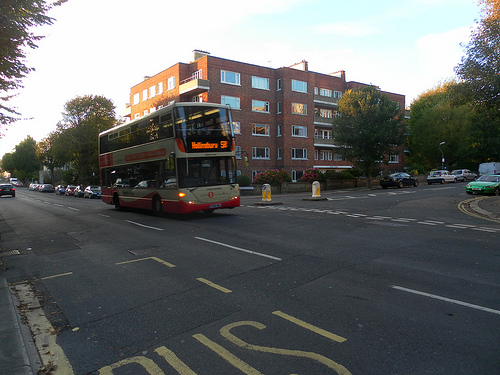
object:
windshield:
[180, 149, 244, 188]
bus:
[98, 98, 249, 220]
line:
[188, 232, 283, 267]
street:
[5, 179, 499, 371]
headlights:
[177, 188, 199, 205]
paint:
[219, 327, 235, 335]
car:
[456, 168, 498, 204]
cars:
[24, 178, 105, 200]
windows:
[218, 71, 241, 86]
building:
[129, 51, 406, 194]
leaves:
[448, 113, 450, 115]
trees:
[457, 0, 499, 168]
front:
[167, 101, 245, 207]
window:
[172, 105, 232, 141]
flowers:
[253, 173, 269, 183]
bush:
[258, 169, 292, 185]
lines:
[99, 211, 162, 232]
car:
[423, 170, 456, 188]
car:
[375, 170, 422, 189]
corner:
[463, 194, 499, 226]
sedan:
[451, 165, 475, 181]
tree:
[324, 79, 408, 201]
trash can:
[311, 180, 322, 199]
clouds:
[306, 16, 438, 77]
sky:
[0, 4, 456, 134]